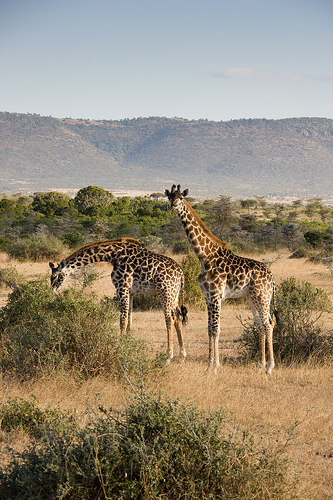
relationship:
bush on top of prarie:
[0, 272, 170, 391] [15, 189, 331, 491]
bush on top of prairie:
[232, 274, 333, 366] [4, 189, 331, 495]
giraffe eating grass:
[49, 236, 194, 367] [1, 182, 332, 498]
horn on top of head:
[170, 184, 175, 191] [164, 182, 189, 208]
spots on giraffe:
[236, 271, 245, 281] [49, 236, 194, 367]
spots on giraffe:
[133, 265, 142, 274] [49, 236, 194, 367]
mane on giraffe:
[175, 194, 232, 248] [163, 184, 280, 374]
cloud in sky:
[209, 59, 249, 82] [0, 1, 323, 103]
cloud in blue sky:
[209, 59, 261, 77] [18, 21, 186, 97]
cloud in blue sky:
[209, 59, 261, 77] [0, 0, 333, 119]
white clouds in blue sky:
[284, 82, 305, 101] [0, 0, 333, 119]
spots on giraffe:
[213, 254, 229, 268] [163, 184, 280, 374]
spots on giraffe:
[155, 255, 174, 284] [163, 184, 280, 374]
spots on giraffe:
[188, 221, 202, 237] [163, 184, 280, 374]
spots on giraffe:
[251, 262, 265, 282] [163, 184, 280, 374]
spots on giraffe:
[120, 248, 144, 271] [163, 184, 280, 374]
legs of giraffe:
[194, 262, 276, 376] [163, 184, 280, 374]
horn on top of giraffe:
[176, 184, 181, 192] [165, 182, 302, 382]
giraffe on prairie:
[163, 184, 280, 374] [0, 189, 333, 499]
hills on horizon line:
[3, 109, 325, 196] [6, 185, 332, 200]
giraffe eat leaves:
[39, 232, 194, 377] [6, 276, 120, 359]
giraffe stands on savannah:
[49, 236, 194, 367] [4, 189, 322, 491]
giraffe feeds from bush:
[49, 236, 194, 367] [2, 275, 132, 376]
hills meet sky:
[4, 106, 331, 191] [109, 67, 188, 111]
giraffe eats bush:
[49, 236, 194, 367] [0, 281, 120, 377]